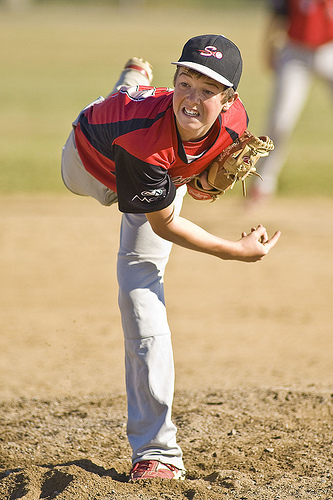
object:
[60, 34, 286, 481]
boy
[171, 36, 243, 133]
head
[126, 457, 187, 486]
shoe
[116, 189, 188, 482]
leg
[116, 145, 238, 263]
arm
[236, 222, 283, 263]
hand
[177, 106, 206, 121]
mouth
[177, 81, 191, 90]
eye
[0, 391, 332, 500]
mound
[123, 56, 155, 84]
spikes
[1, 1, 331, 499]
infield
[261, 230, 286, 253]
finger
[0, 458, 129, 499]
shadow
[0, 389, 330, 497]
dirt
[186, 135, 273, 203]
glove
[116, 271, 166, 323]
knee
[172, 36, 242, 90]
hat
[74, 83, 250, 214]
jersey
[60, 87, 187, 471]
pants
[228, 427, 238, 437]
rock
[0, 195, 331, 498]
ground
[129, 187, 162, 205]
letters